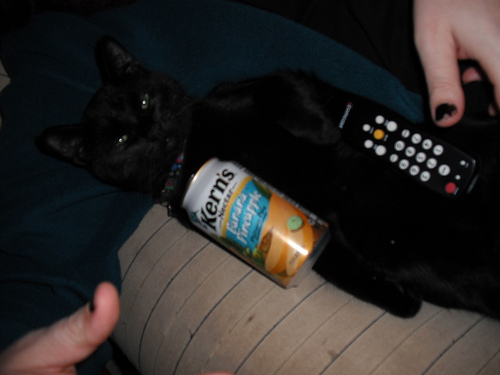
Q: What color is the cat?
A: Black.